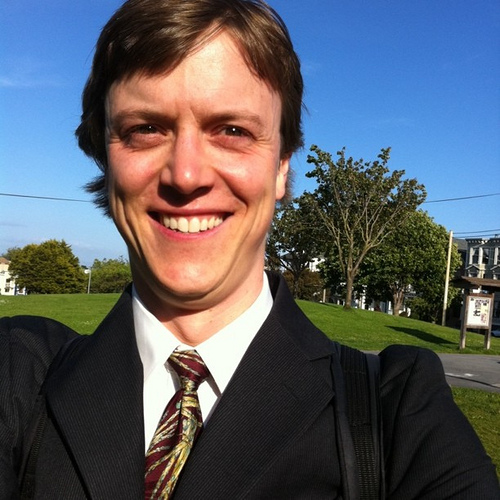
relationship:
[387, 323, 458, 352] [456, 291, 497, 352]
shadow of board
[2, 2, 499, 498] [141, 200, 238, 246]
man has smile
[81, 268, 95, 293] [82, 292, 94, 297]
flag in hole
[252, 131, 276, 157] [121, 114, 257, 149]
wrinkles around eyes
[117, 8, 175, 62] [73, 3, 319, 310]
hair on head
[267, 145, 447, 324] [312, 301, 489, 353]
trees in background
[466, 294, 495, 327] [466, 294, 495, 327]
sign has sign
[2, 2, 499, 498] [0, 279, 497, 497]
man in suit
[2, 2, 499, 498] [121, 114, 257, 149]
man has eyes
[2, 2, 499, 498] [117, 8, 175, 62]
man has hair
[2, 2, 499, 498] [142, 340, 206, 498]
man wearing tie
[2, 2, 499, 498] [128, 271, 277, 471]
man wearing shirt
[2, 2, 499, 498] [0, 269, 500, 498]
man wearing jacket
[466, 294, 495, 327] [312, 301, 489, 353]
sign in background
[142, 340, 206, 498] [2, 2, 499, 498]
tie on man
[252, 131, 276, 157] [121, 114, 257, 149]
wrinkles on eyes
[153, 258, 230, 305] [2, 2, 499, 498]
chin on guy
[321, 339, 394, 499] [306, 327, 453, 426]
strap on shoulder